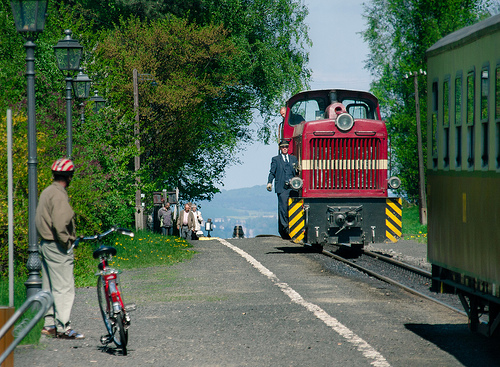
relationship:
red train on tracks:
[262, 76, 427, 276] [352, 242, 473, 326]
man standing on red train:
[271, 137, 302, 237] [275, 86, 405, 251]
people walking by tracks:
[156, 191, 216, 241] [329, 234, 487, 318]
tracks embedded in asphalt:
[352, 242, 473, 326] [2, 219, 487, 364]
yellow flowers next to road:
[106, 237, 199, 272] [198, 216, 493, 365]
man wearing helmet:
[36, 155, 87, 341] [46, 153, 77, 177]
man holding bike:
[36, 155, 87, 341] [67, 220, 137, 356]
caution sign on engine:
[280, 189, 406, 247] [240, 80, 418, 262]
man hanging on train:
[266, 140, 301, 242] [255, 90, 395, 251]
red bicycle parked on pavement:
[74, 235, 177, 353] [81, 258, 306, 351]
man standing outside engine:
[266, 140, 301, 242] [261, 85, 399, 253]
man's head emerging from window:
[267, 100, 303, 136] [286, 97, 325, 128]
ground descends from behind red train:
[235, 236, 281, 266] [275, 86, 405, 251]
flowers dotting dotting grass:
[100, 226, 194, 270] [128, 225, 165, 262]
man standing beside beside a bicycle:
[18, 147, 93, 341] [15, 133, 93, 343]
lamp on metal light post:
[8, 4, 46, 46] [24, 40, 43, 297]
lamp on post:
[69, 68, 100, 105] [74, 97, 95, 135]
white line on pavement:
[208, 234, 407, 365] [215, 250, 340, 349]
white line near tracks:
[208, 234, 407, 365] [330, 237, 414, 286]